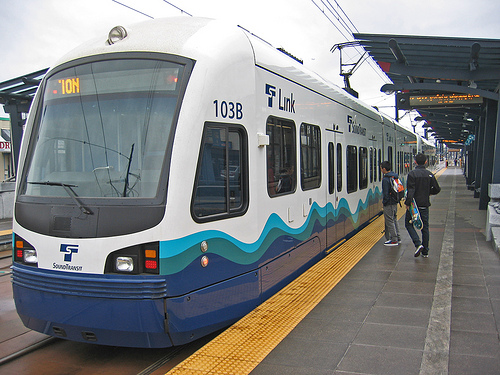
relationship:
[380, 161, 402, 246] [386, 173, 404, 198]
boy wears backpack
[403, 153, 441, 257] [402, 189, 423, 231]
boy holds skateboard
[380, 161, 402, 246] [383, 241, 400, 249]
boy wears shoes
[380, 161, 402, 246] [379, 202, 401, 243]
boy wears pants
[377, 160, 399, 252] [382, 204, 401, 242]
boy wears leg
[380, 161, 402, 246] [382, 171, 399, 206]
boy wears jacket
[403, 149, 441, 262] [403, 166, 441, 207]
boy wears jacket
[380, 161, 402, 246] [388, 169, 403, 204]
boy wears backpack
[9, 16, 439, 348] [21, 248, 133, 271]
train has headlight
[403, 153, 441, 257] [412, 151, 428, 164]
boy has hair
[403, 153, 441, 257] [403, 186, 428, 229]
boy carrying skateboard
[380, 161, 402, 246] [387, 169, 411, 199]
boy carrying backpack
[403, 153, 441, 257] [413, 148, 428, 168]
boy has head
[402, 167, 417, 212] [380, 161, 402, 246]
arm of boy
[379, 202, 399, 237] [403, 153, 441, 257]
leg of boy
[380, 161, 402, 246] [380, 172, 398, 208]
boy wearing jacket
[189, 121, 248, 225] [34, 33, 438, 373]
window of train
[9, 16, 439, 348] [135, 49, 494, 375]
train at station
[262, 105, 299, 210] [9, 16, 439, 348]
window on train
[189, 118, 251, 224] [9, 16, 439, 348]
window on train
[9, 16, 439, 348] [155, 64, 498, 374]
train at station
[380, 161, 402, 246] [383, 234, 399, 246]
boy wearing shoes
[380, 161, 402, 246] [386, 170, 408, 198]
boy wearing backpack